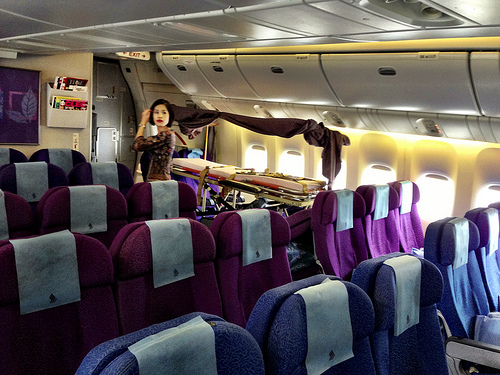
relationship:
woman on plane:
[138, 75, 182, 183] [43, 29, 488, 373]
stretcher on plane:
[186, 151, 315, 193] [43, 29, 488, 373]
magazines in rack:
[44, 73, 117, 96] [48, 76, 96, 135]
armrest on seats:
[441, 328, 498, 374] [147, 183, 498, 372]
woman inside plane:
[138, 75, 182, 183] [43, 29, 488, 373]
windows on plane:
[244, 147, 499, 226] [43, 29, 488, 373]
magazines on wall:
[44, 73, 117, 96] [48, 51, 87, 154]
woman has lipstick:
[138, 75, 182, 183] [158, 118, 165, 126]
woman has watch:
[138, 75, 182, 183] [131, 117, 152, 133]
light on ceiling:
[370, 0, 445, 26] [5, 8, 494, 55]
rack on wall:
[48, 76, 96, 135] [48, 51, 87, 154]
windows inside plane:
[244, 147, 499, 226] [43, 29, 488, 373]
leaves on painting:
[10, 92, 39, 131] [3, 68, 52, 149]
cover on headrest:
[287, 264, 350, 363] [266, 267, 366, 367]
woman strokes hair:
[138, 75, 182, 183] [149, 104, 178, 130]